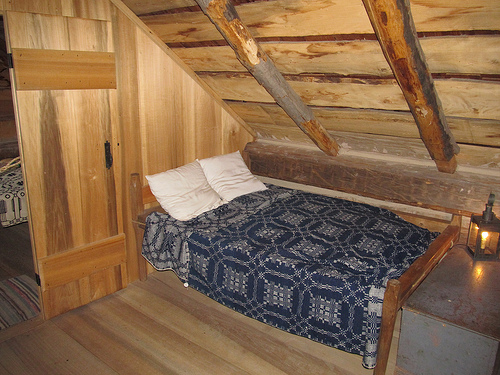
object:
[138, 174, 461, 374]
bed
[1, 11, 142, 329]
door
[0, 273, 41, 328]
rug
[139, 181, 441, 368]
bed spread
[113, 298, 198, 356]
person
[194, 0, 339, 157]
log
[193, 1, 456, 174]
wooden supports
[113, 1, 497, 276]
wall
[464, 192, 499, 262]
bulb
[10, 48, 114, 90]
wood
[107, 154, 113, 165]
knob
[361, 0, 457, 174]
exposed log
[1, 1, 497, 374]
bedroom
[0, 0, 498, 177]
board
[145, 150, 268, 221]
pillow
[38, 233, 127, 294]
support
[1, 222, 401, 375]
floor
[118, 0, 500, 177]
roof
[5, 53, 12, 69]
hinge